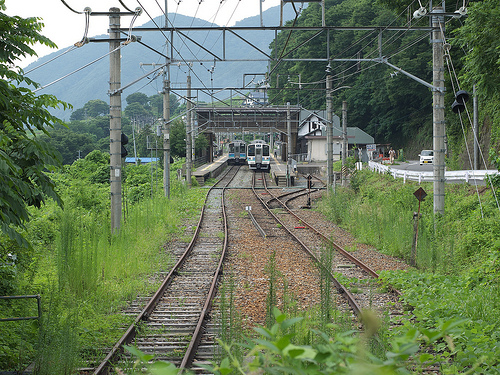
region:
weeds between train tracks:
[177, 233, 376, 373]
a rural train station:
[161, 77, 437, 220]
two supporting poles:
[78, 8, 467, 233]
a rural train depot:
[282, 83, 397, 190]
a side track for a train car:
[239, 136, 334, 234]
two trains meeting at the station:
[195, 122, 288, 200]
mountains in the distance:
[34, 0, 404, 204]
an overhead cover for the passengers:
[179, 87, 308, 140]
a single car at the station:
[314, 129, 445, 185]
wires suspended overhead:
[127, 3, 327, 30]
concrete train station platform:
[192, 150, 227, 183]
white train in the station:
[245, 136, 272, 166]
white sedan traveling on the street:
[415, 145, 435, 165]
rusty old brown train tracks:
[87, 160, 238, 370]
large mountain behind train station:
[36, 10, 271, 120]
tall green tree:
[0, 0, 62, 290]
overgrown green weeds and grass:
[311, 152, 496, 372]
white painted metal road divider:
[350, 160, 495, 190]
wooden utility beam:
[75, 5, 140, 240]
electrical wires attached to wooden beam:
[28, 3, 140, 93]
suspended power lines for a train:
[171, 17, 247, 21]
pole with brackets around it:
[101, 62, 135, 227]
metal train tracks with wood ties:
[171, 240, 209, 340]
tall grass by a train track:
[328, 195, 390, 257]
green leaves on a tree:
[6, 92, 43, 163]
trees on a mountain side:
[78, 73, 101, 93]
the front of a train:
[248, 145, 273, 167]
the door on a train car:
[253, 147, 261, 164]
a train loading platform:
[209, 157, 222, 182]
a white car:
[413, 147, 438, 164]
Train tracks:
[92, 173, 464, 374]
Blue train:
[216, 135, 246, 175]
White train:
[243, 138, 278, 170]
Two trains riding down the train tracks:
[91, 119, 433, 371]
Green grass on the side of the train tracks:
[0, 121, 180, 371]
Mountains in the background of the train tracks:
[0, 4, 329, 100]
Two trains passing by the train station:
[181, 91, 379, 186]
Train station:
[274, 100, 409, 182]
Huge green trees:
[272, 4, 498, 138]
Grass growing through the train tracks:
[73, 230, 476, 372]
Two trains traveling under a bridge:
[217, 132, 284, 179]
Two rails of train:
[80, 166, 451, 372]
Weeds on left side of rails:
[10, 140, 185, 360]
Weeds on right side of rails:
[380, 155, 490, 340]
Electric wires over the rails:
[12, 1, 432, 92]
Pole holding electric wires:
[90, 1, 148, 261]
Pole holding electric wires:
[421, 7, 459, 224]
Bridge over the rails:
[168, 105, 308, 137]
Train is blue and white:
[218, 137, 252, 167]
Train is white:
[242, 132, 273, 174]